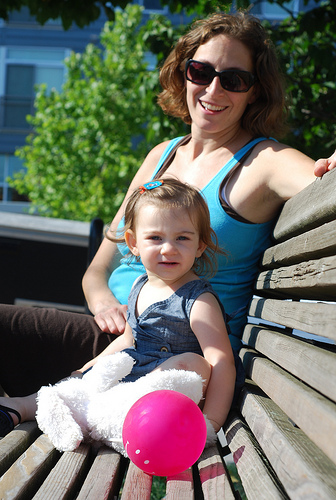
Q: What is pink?
A: Balloon.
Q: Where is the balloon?
A: Bench.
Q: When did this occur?
A: Daytime.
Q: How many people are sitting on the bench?
A: Two.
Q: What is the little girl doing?
A: Sitting.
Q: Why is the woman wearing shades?
A: Sunny.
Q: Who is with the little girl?
A: Woman.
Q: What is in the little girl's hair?
A: Barrette.